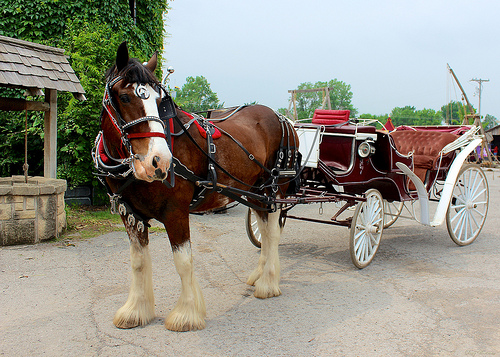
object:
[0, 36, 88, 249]
well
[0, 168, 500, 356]
sidewalk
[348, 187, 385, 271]
wheel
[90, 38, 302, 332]
horse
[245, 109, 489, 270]
wagon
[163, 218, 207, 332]
leg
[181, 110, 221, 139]
saddle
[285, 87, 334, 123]
frame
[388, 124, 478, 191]
seat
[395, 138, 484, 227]
footpiece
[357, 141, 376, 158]
horn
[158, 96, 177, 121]
blinders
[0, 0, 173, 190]
vines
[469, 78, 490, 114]
pole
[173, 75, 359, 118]
top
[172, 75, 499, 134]
trees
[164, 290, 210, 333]
foot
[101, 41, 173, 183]
head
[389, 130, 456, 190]
red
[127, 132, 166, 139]
strap